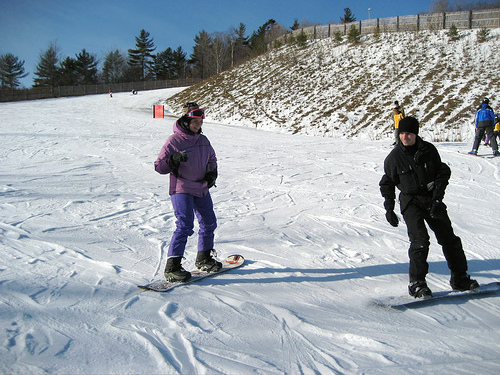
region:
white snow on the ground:
[90, 301, 317, 368]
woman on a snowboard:
[139, 97, 256, 307]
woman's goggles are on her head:
[170, 95, 215, 139]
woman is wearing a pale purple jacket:
[148, 93, 228, 201]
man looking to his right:
[374, 104, 450, 206]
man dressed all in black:
[370, 107, 496, 320]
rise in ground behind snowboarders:
[176, 27, 494, 217]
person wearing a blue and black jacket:
[463, 93, 498, 146]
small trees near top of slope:
[265, 20, 494, 52]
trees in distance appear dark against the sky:
[2, 0, 362, 85]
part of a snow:
[332, 289, 379, 335]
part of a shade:
[313, 238, 367, 294]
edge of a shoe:
[396, 275, 437, 302]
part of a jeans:
[173, 220, 195, 255]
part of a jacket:
[186, 180, 195, 187]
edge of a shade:
[293, 265, 340, 321]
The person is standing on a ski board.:
[156, 109, 241, 299]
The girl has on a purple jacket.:
[153, 132, 243, 189]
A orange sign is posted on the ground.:
[147, 94, 170, 120]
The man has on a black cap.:
[388, 119, 419, 134]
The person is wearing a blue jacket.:
[465, 88, 496, 139]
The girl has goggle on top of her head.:
[186, 106, 221, 121]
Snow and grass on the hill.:
[246, 46, 417, 131]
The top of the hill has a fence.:
[278, 13, 493, 43]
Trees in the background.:
[16, 36, 211, 83]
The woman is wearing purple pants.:
[158, 187, 235, 244]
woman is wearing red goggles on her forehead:
[150, 105, 220, 276]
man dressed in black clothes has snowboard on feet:
[375, 115, 475, 295]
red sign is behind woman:
[152, 102, 164, 120]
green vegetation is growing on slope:
[267, 19, 494, 55]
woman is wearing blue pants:
[160, 187, 237, 250]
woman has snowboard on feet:
[140, 254, 250, 292]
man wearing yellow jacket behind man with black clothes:
[390, 107, 403, 134]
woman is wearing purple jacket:
[153, 121, 221, 194]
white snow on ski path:
[20, 120, 114, 274]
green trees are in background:
[2, 24, 218, 80]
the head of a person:
[176, 94, 215, 140]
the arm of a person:
[150, 135, 179, 172]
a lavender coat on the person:
[148, 112, 221, 199]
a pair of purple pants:
[163, 185, 228, 260]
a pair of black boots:
[163, 245, 223, 285]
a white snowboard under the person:
[138, 247, 245, 298]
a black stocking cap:
[393, 110, 426, 138]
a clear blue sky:
[0, 0, 497, 90]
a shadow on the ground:
[200, 249, 497, 295]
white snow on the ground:
[3, 78, 499, 373]